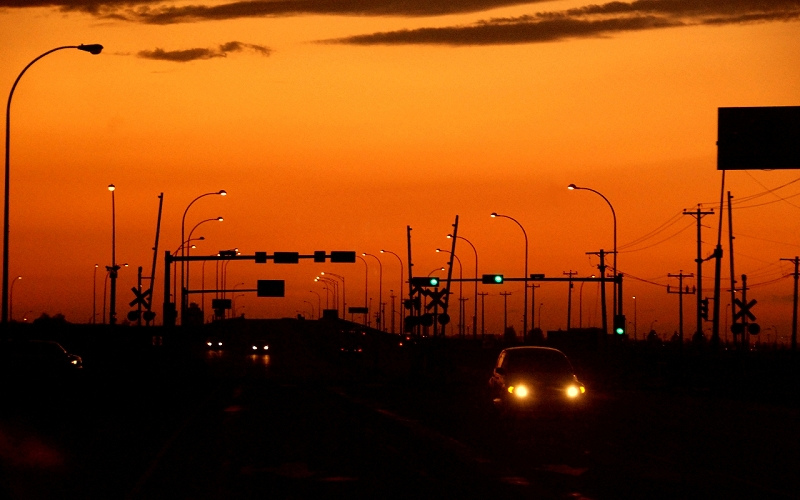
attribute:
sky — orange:
[253, 184, 299, 237]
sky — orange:
[27, 102, 124, 178]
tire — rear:
[476, 374, 498, 409]